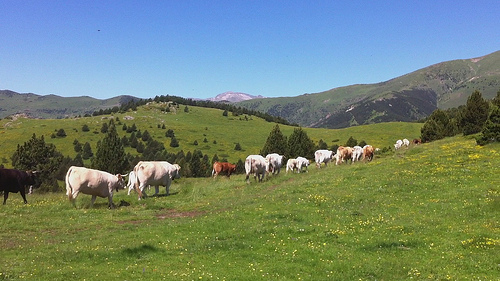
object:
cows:
[66, 165, 131, 210]